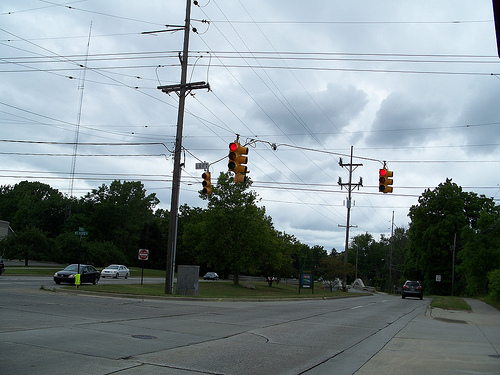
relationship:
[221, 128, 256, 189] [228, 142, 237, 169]
signal a signal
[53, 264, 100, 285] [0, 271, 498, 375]
car on a road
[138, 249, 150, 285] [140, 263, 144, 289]
sign on a post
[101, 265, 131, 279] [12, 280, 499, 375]
car approaches intersection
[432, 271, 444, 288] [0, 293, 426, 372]
traffic sign next to street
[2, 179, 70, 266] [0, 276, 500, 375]
round tree next to intersection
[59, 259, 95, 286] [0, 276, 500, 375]
car driving on intersection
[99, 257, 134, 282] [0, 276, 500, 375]
car driving on intersection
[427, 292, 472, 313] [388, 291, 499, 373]
grass area on sidewalk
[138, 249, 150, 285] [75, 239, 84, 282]
sign on post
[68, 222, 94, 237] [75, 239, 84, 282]
street sign on post